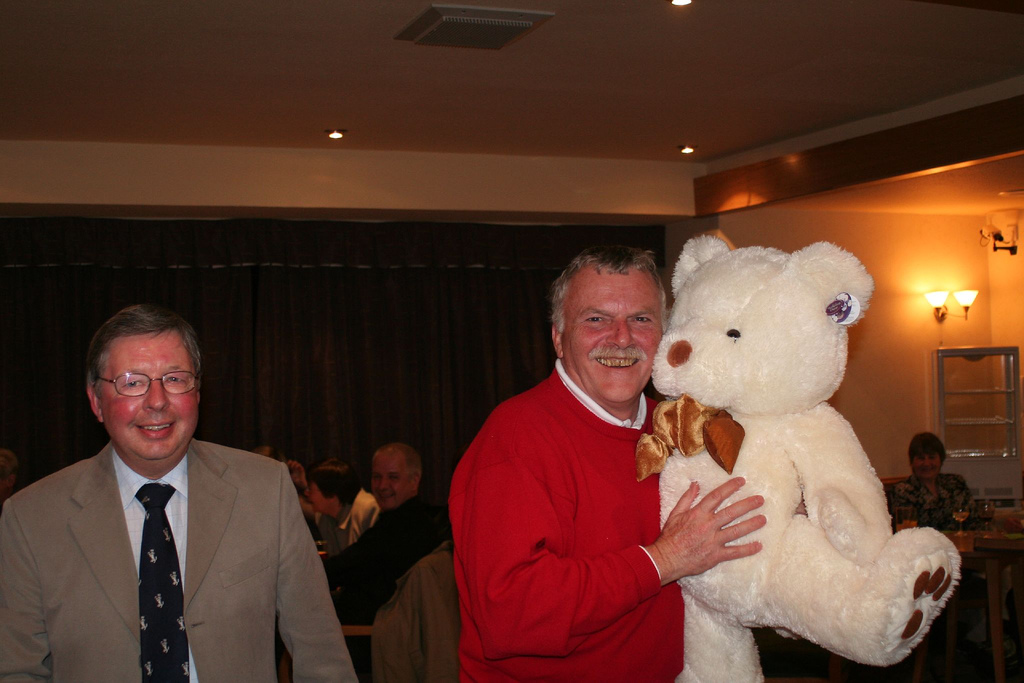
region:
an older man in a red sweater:
[455, 179, 680, 674]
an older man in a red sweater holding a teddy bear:
[457, 214, 868, 677]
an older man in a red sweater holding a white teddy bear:
[465, 206, 937, 584]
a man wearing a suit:
[2, 291, 369, 671]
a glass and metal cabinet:
[917, 334, 1017, 499]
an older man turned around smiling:
[336, 441, 425, 540]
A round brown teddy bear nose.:
[667, 337, 693, 364]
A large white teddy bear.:
[640, 231, 960, 680]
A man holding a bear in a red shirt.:
[447, 241, 774, 681]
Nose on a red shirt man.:
[607, 320, 636, 353]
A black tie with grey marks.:
[134, 479, 193, 680]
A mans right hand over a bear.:
[667, 475, 769, 580]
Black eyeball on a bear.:
[725, 324, 742, 341]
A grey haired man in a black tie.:
[3, 307, 362, 681]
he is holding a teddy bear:
[454, 154, 992, 673]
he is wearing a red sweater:
[390, 165, 776, 672]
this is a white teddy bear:
[637, 176, 973, 663]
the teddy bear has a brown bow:
[473, 149, 957, 680]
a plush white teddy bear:
[665, 132, 985, 673]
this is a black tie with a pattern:
[121, 481, 217, 678]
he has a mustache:
[434, 174, 736, 675]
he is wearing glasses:
[43, 297, 334, 675]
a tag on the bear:
[817, 275, 885, 355]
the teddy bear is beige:
[652, 232, 963, 676]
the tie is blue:
[127, 481, 189, 672]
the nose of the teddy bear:
[664, 334, 693, 369]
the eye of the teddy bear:
[722, 318, 752, 348]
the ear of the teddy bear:
[781, 241, 871, 328]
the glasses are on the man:
[87, 370, 195, 391]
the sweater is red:
[443, 370, 678, 675]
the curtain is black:
[1, 215, 656, 510]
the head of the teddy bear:
[648, 232, 868, 406]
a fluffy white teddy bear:
[654, 233, 961, 679]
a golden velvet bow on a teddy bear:
[632, 391, 741, 480]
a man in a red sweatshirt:
[442, 241, 774, 679]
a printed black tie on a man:
[134, 479, 195, 679]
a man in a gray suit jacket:
[0, 298, 356, 679]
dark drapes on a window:
[0, 222, 667, 524]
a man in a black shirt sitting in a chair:
[312, 441, 452, 620]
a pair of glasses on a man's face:
[87, 366, 196, 398]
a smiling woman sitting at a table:
[891, 435, 978, 531]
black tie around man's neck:
[104, 481, 225, 653]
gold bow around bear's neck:
[635, 394, 756, 474]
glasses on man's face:
[88, 353, 235, 407]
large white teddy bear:
[613, 198, 978, 652]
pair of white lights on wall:
[907, 271, 991, 330]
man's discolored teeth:
[578, 344, 665, 383]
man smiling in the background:
[291, 423, 448, 569]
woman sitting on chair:
[871, 406, 1008, 544]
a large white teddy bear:
[789, 338, 976, 656]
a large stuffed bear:
[620, 288, 915, 674]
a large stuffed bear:
[596, 218, 856, 671]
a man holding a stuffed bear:
[424, 268, 816, 668]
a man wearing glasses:
[17, 285, 371, 677]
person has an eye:
[125, 380, 139, 385]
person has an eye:
[168, 376, 185, 386]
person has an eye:
[585, 312, 605, 323]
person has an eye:
[630, 312, 649, 322]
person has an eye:
[390, 476, 401, 481]